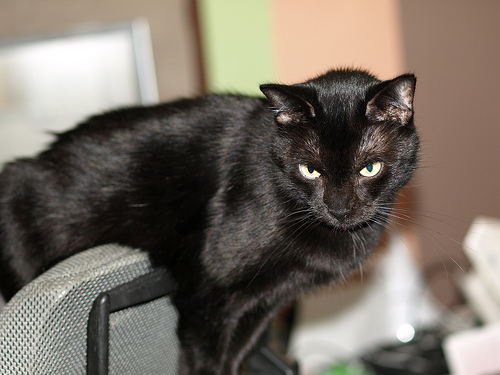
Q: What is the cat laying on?
A: Chair.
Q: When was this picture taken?
A: Daytime.